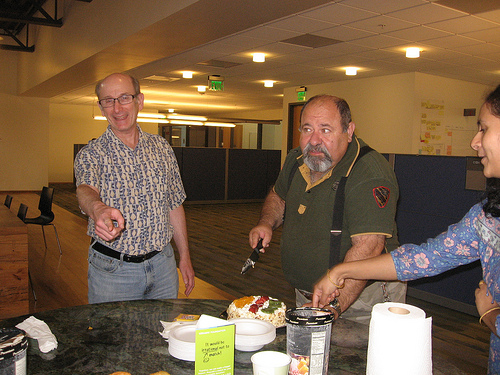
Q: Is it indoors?
A: Yes, it is indoors.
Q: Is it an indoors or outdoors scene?
A: It is indoors.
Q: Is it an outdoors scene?
A: No, it is indoors.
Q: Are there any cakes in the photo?
A: Yes, there is a cake.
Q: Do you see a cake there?
A: Yes, there is a cake.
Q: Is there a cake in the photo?
A: Yes, there is a cake.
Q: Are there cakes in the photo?
A: Yes, there is a cake.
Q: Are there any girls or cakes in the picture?
A: Yes, there is a cake.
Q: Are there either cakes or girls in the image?
A: Yes, there is a cake.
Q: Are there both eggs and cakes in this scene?
A: No, there is a cake but no eggs.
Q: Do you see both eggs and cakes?
A: No, there is a cake but no eggs.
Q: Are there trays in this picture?
A: No, there are no trays.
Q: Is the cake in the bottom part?
A: Yes, the cake is in the bottom of the image.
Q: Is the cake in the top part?
A: No, the cake is in the bottom of the image.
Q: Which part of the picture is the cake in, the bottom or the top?
A: The cake is in the bottom of the image.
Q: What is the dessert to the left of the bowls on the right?
A: The dessert is a cake.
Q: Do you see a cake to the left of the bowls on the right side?
A: Yes, there is a cake to the left of the bowls.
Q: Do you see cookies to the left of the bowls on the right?
A: No, there is a cake to the left of the bowls.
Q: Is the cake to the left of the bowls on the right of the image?
A: Yes, the cake is to the left of the bowls.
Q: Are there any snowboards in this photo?
A: No, there are no snowboards.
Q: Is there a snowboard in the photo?
A: No, there are no snowboards.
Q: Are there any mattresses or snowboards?
A: No, there are no snowboards or mattresses.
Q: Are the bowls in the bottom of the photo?
A: Yes, the bowls are in the bottom of the image.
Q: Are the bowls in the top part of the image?
A: No, the bowls are in the bottom of the image.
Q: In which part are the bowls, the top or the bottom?
A: The bowls are in the bottom of the image.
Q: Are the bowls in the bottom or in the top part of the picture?
A: The bowls are in the bottom of the image.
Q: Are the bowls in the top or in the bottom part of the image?
A: The bowls are in the bottom of the image.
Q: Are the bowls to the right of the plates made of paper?
A: Yes, the bowls are made of paper.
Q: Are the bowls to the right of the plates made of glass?
A: No, the bowls are made of paper.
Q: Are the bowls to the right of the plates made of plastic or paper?
A: The bowls are made of paper.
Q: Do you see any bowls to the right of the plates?
A: Yes, there are bowls to the right of the plates.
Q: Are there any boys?
A: No, there are no boys.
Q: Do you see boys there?
A: No, there are no boys.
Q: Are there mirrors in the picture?
A: No, there are no mirrors.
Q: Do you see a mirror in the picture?
A: No, there are no mirrors.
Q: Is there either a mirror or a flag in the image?
A: No, there are no mirrors or flags.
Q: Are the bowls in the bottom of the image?
A: Yes, the bowls are in the bottom of the image.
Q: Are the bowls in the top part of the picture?
A: No, the bowls are in the bottom of the image.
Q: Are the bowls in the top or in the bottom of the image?
A: The bowls are in the bottom of the image.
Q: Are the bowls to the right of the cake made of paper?
A: Yes, the bowls are made of paper.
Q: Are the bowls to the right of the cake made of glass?
A: No, the bowls are made of paper.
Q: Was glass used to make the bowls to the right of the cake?
A: No, the bowls are made of paper.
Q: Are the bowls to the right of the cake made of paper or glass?
A: The bowls are made of paper.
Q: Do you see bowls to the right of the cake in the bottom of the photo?
A: Yes, there are bowls to the right of the cake.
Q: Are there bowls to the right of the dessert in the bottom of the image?
A: Yes, there are bowls to the right of the cake.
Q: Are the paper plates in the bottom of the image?
A: Yes, the plates are in the bottom of the image.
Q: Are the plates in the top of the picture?
A: No, the plates are in the bottom of the image.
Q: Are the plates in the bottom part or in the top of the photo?
A: The plates are in the bottom of the image.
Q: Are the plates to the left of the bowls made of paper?
A: Yes, the plates are made of paper.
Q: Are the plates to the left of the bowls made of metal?
A: No, the plates are made of paper.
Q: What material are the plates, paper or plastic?
A: The plates are made of paper.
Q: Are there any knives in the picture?
A: Yes, there is a knife.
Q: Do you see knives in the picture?
A: Yes, there is a knife.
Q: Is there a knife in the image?
A: Yes, there is a knife.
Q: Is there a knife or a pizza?
A: Yes, there is a knife.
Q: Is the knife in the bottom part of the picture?
A: Yes, the knife is in the bottom of the image.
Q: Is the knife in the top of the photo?
A: No, the knife is in the bottom of the image.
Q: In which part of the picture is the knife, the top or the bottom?
A: The knife is in the bottom of the image.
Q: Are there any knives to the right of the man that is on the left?
A: Yes, there is a knife to the right of the man.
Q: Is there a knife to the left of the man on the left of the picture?
A: No, the knife is to the right of the man.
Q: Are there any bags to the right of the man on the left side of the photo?
A: No, there is a knife to the right of the man.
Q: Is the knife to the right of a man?
A: Yes, the knife is to the right of a man.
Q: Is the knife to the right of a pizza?
A: No, the knife is to the right of a man.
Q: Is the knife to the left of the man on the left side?
A: No, the knife is to the right of the man.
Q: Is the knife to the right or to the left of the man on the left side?
A: The knife is to the right of the man.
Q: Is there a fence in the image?
A: No, there are no fences.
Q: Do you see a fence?
A: No, there are no fences.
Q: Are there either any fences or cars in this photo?
A: No, there are no fences or cars.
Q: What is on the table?
A: The sign is on the table.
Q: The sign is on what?
A: The sign is on the table.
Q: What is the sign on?
A: The sign is on the table.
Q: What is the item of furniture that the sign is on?
A: The piece of furniture is a table.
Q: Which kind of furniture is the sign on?
A: The sign is on the table.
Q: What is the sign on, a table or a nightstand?
A: The sign is on a table.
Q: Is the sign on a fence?
A: No, the sign is on a table.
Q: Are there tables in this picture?
A: Yes, there is a table.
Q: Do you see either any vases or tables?
A: Yes, there is a table.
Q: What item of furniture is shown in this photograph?
A: The piece of furniture is a table.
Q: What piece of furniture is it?
A: The piece of furniture is a table.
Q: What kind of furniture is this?
A: This is a table.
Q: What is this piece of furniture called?
A: This is a table.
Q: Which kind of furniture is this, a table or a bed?
A: This is a table.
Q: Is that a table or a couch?
A: That is a table.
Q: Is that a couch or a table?
A: That is a table.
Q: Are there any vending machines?
A: No, there are no vending machines.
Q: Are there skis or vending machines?
A: No, there are no vending machines or skis.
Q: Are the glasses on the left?
A: Yes, the glasses are on the left of the image.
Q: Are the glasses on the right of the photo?
A: No, the glasses are on the left of the image.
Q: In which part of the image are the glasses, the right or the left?
A: The glasses are on the left of the image.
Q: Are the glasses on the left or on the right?
A: The glasses are on the left of the image.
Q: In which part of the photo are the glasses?
A: The glasses are on the left of the image.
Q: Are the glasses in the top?
A: Yes, the glasses are in the top of the image.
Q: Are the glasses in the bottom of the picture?
A: No, the glasses are in the top of the image.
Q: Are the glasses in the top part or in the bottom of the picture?
A: The glasses are in the top of the image.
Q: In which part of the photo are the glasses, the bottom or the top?
A: The glasses are in the top of the image.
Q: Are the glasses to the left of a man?
A: Yes, the glasses are to the left of a man.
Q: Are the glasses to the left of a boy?
A: No, the glasses are to the left of a man.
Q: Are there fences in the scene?
A: No, there are no fences.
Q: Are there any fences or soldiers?
A: No, there are no fences or soldiers.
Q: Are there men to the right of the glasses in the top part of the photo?
A: Yes, there is a man to the right of the glasses.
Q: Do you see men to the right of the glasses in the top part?
A: Yes, there is a man to the right of the glasses.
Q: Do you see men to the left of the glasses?
A: No, the man is to the right of the glasses.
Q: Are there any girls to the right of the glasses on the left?
A: No, there is a man to the right of the glasses.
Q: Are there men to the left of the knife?
A: Yes, there is a man to the left of the knife.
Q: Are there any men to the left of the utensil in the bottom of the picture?
A: Yes, there is a man to the left of the knife.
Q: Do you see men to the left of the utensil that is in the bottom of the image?
A: Yes, there is a man to the left of the knife.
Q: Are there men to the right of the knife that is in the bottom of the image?
A: No, the man is to the left of the knife.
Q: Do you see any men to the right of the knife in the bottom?
A: No, the man is to the left of the knife.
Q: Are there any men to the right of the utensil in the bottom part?
A: No, the man is to the left of the knife.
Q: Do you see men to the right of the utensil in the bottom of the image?
A: No, the man is to the left of the knife.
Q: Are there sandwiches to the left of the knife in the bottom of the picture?
A: No, there is a man to the left of the knife.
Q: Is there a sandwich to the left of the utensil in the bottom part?
A: No, there is a man to the left of the knife.